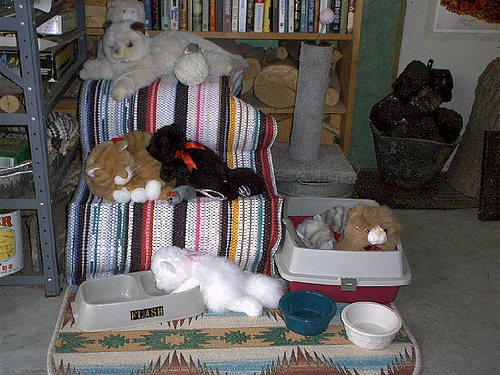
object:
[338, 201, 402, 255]
animal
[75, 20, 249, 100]
animal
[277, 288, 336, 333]
water bowl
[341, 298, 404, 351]
water bowl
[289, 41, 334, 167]
carpet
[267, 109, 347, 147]
firewood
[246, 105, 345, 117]
shelf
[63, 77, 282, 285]
blanket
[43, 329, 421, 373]
towel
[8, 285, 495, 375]
floor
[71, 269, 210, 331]
food dish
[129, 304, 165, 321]
woods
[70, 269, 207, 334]
dish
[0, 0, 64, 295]
shelf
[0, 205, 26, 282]
can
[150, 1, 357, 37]
books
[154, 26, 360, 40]
shelf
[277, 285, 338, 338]
bowl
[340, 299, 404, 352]
bowl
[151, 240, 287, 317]
animal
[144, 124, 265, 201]
animal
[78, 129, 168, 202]
cat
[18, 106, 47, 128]
corner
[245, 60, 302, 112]
cut logs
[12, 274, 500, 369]
light/gray floor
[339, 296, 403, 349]
food dish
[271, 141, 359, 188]
grey carpet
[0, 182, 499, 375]
carpet